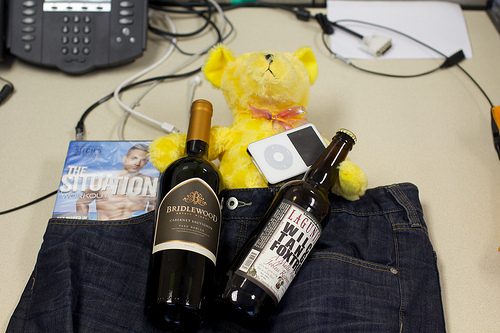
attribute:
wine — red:
[157, 90, 218, 320]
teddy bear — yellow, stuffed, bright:
[155, 48, 363, 199]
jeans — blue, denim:
[6, 183, 444, 331]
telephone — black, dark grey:
[5, 0, 146, 75]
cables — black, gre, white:
[76, 6, 467, 134]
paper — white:
[326, 2, 467, 61]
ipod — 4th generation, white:
[245, 125, 326, 185]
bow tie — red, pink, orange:
[248, 107, 305, 129]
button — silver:
[224, 196, 242, 212]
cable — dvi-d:
[323, 18, 396, 61]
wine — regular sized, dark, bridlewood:
[144, 99, 226, 328]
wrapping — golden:
[180, 97, 214, 146]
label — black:
[150, 181, 218, 264]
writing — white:
[165, 203, 218, 222]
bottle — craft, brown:
[220, 126, 359, 320]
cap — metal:
[336, 130, 360, 143]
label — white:
[234, 201, 322, 306]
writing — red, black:
[266, 210, 320, 273]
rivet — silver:
[390, 265, 400, 276]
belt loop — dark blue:
[387, 185, 422, 229]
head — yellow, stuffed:
[209, 41, 319, 115]